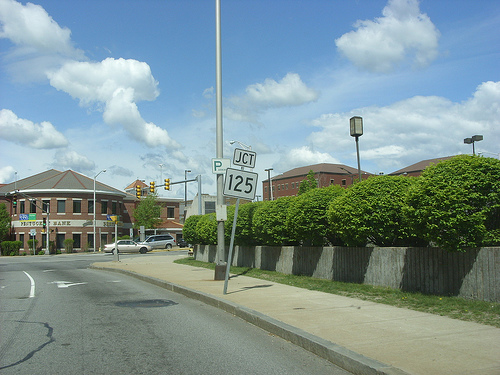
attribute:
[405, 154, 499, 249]
bush — green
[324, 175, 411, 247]
bush — green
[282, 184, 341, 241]
bush — green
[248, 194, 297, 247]
bush — green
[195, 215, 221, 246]
bush — green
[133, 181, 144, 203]
traffic light — yellow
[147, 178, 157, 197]
traffic light — yellow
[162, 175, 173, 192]
traffic light — yellow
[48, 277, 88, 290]
arrow — white, for right turn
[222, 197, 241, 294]
pillar — small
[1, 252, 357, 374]
road — clean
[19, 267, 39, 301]
line — white, small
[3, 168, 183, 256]
building — big, neat, round shaped, brick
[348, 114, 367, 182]
light — black, tall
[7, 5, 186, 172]
clouds — fluffy, white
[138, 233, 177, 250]
minivan — silver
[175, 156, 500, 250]
hedges — rounded, green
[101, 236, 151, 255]
sedan — gold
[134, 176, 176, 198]
stoplights — yellow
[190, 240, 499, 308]
wall — wooden, gray, cement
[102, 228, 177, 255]
vehicles — passing each other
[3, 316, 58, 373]
crack — black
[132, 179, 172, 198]
traffic lights — a group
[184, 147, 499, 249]
bushes — green, uniform trimmed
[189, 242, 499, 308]
fence — wooden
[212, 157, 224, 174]
letter p — green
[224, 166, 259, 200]
sign — black, white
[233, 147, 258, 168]
sign — black, white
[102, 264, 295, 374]
curb — large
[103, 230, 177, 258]
cars — driving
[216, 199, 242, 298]
street pole — tilted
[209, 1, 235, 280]
electric pole — very long